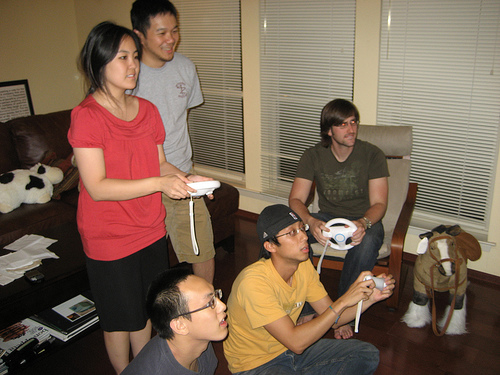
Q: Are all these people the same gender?
A: No, they are both male and female.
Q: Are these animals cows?
A: No, they are horses and cows.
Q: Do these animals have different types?
A: Yes, they are horses and cows.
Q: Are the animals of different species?
A: Yes, they are horses and cows.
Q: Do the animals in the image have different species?
A: Yes, they are horses and cows.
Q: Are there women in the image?
A: Yes, there is a woman.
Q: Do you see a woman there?
A: Yes, there is a woman.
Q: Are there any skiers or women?
A: Yes, there is a woman.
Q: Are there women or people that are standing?
A: Yes, the woman is standing.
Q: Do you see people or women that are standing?
A: Yes, the woman is standing.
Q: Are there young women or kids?
A: Yes, there is a young woman.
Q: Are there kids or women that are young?
A: Yes, the woman is young.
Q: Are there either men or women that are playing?
A: Yes, the woman is playing.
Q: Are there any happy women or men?
A: Yes, there is a happy woman.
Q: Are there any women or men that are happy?
A: Yes, the woman is happy.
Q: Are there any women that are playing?
A: Yes, there is a woman that is playing.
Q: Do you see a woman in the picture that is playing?
A: Yes, there is a woman that is playing.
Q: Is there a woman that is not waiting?
A: Yes, there is a woman that is playing.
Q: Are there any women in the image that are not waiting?
A: Yes, there is a woman that is playing.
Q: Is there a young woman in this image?
A: Yes, there is a young woman.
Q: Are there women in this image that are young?
A: Yes, there is a woman that is young.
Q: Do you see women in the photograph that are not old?
A: Yes, there is an young woman.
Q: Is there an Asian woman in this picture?
A: Yes, there is an Asian woman.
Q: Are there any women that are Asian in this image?
A: Yes, there is an Asian woman.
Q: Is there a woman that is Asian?
A: Yes, there is a woman that is asian.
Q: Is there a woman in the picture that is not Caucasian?
A: Yes, there is a Asian woman.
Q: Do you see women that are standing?
A: Yes, there is a woman that is standing.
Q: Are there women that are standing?
A: Yes, there is a woman that is standing.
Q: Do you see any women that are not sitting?
A: Yes, there is a woman that is standing .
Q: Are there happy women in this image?
A: Yes, there is a happy woman.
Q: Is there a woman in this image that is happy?
A: Yes, there is a woman that is happy.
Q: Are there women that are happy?
A: Yes, there is a woman that is happy.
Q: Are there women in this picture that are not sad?
A: Yes, there is a happy woman.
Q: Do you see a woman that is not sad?
A: Yes, there is a happy woman.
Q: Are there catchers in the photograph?
A: No, there are no catchers.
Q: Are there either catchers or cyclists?
A: No, there are no catchers or cyclists.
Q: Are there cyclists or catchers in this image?
A: No, there are no catchers or cyclists.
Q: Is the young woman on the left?
A: Yes, the woman is on the left of the image.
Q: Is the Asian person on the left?
A: Yes, the woman is on the left of the image.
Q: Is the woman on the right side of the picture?
A: No, the woman is on the left of the image.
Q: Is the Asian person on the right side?
A: No, the woman is on the left of the image.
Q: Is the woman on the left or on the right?
A: The woman is on the left of the image.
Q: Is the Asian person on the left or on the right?
A: The woman is on the left of the image.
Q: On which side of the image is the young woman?
A: The woman is on the left of the image.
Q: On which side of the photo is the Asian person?
A: The woman is on the left of the image.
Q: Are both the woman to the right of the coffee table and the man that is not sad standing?
A: Yes, both the woman and the man are standing.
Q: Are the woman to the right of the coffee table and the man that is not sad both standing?
A: Yes, both the woman and the man are standing.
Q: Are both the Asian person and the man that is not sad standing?
A: Yes, both the woman and the man are standing.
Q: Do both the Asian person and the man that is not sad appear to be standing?
A: Yes, both the woman and the man are standing.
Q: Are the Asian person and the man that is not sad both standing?
A: Yes, both the woman and the man are standing.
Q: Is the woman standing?
A: Yes, the woman is standing.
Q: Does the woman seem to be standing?
A: Yes, the woman is standing.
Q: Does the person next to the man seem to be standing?
A: Yes, the woman is standing.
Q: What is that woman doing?
A: The woman is standing.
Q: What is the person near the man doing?
A: The woman is standing.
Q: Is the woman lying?
A: No, the woman is standing.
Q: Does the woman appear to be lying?
A: No, the woman is standing.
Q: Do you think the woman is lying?
A: No, the woman is standing.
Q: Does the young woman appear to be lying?
A: No, the woman is standing.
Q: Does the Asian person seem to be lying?
A: No, the woman is standing.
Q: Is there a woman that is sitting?
A: No, there is a woman but she is standing.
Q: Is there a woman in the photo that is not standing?
A: No, there is a woman but she is standing.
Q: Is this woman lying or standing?
A: The woman is standing.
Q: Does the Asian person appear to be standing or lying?
A: The woman is standing.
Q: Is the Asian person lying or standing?
A: The woman is standing.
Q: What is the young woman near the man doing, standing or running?
A: The woman is standing.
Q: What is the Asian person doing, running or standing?
A: The woman is standing.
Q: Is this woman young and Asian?
A: Yes, the woman is young and asian.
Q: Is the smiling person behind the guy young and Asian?
A: Yes, the woman is young and asian.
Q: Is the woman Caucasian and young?
A: No, the woman is young but asian.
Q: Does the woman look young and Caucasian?
A: No, the woman is young but asian.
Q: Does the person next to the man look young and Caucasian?
A: No, the woman is young but asian.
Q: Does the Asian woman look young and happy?
A: Yes, the woman is young and happy.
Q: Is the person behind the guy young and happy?
A: Yes, the woman is young and happy.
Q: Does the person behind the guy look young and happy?
A: Yes, the woman is young and happy.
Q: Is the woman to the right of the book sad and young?
A: No, the woman is young but happy.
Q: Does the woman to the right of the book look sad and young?
A: No, the woman is young but happy.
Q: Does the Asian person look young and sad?
A: No, the woman is young but happy.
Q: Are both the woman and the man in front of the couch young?
A: Yes, both the woman and the man are young.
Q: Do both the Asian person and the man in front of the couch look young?
A: Yes, both the woman and the man are young.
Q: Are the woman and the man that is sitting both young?
A: Yes, both the woman and the man are young.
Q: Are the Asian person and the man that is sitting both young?
A: Yes, both the woman and the man are young.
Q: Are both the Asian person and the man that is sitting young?
A: Yes, both the woman and the man are young.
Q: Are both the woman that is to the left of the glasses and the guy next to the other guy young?
A: Yes, both the woman and the guy are young.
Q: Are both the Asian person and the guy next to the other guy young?
A: Yes, both the woman and the guy are young.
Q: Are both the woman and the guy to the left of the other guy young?
A: Yes, both the woman and the guy are young.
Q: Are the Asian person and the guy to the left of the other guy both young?
A: Yes, both the woman and the guy are young.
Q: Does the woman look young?
A: Yes, the woman is young.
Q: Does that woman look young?
A: Yes, the woman is young.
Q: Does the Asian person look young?
A: Yes, the woman is young.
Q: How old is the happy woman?
A: The woman is young.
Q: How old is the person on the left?
A: The woman is young.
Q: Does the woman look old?
A: No, the woman is young.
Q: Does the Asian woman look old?
A: No, the woman is young.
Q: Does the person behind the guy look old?
A: No, the woman is young.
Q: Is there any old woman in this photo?
A: No, there is a woman but she is young.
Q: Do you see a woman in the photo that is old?
A: No, there is a woman but she is young.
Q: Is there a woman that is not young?
A: No, there is a woman but she is young.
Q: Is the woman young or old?
A: The woman is young.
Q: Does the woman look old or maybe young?
A: The woman is young.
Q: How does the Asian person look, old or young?
A: The woman is young.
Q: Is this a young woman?
A: Yes, this is a young woman.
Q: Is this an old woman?
A: No, this is a young woman.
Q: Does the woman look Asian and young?
A: Yes, the woman is Asian and young.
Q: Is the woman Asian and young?
A: Yes, the woman is Asian and young.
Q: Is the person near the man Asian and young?
A: Yes, the woman is Asian and young.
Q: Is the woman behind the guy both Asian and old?
A: No, the woman is Asian but young.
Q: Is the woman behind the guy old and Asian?
A: No, the woman is Asian but young.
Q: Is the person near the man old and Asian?
A: No, the woman is Asian but young.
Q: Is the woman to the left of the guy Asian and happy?
A: Yes, the woman is Asian and happy.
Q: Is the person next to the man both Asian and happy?
A: Yes, the woman is Asian and happy.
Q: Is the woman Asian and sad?
A: No, the woman is Asian but happy.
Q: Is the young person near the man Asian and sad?
A: No, the woman is Asian but happy.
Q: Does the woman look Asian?
A: Yes, the woman is asian.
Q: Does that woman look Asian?
A: Yes, the woman is asian.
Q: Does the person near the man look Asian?
A: Yes, the woman is asian.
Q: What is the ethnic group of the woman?
A: The woman is asian.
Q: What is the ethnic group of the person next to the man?
A: The woman is asian.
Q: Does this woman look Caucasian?
A: No, the woman is asian.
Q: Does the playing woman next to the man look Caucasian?
A: No, the woman is asian.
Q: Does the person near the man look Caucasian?
A: No, the woman is asian.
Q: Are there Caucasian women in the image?
A: No, there is a woman but she is asian.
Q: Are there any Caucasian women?
A: No, there is a woman but she is asian.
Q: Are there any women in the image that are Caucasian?
A: No, there is a woman but she is asian.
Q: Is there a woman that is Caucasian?
A: No, there is a woman but she is asian.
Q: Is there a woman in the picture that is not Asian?
A: No, there is a woman but she is asian.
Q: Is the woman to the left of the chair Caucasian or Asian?
A: The woman is asian.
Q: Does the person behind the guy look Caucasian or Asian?
A: The woman is asian.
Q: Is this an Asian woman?
A: Yes, this is an Asian woman.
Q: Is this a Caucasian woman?
A: No, this is an Asian woman.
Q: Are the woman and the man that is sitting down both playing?
A: Yes, both the woman and the man are playing.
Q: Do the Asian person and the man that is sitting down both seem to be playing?
A: Yes, both the woman and the man are playing.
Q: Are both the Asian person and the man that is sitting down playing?
A: Yes, both the woman and the man are playing.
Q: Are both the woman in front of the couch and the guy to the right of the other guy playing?
A: Yes, both the woman and the guy are playing.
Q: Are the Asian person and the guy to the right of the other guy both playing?
A: Yes, both the woman and the guy are playing.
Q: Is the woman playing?
A: Yes, the woman is playing.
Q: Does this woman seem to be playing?
A: Yes, the woman is playing.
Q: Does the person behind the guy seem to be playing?
A: Yes, the woman is playing.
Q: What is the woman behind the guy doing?
A: The woman is playing.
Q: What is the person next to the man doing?
A: The woman is playing.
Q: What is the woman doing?
A: The woman is playing.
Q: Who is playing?
A: The woman is playing.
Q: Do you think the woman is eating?
A: No, the woman is playing.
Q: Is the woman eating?
A: No, the woman is playing.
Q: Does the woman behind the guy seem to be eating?
A: No, the woman is playing.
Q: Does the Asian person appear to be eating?
A: No, the woman is playing.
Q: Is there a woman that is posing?
A: No, there is a woman but she is playing.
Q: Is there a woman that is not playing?
A: No, there is a woman but she is playing.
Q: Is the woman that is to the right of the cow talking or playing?
A: The woman is playing.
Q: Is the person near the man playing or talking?
A: The woman is playing.